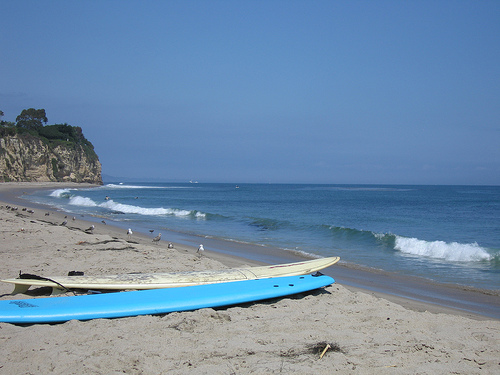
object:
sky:
[1, 1, 499, 184]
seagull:
[195, 243, 206, 254]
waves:
[384, 235, 495, 265]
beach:
[2, 208, 499, 373]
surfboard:
[2, 269, 337, 327]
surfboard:
[3, 254, 341, 290]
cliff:
[0, 106, 105, 188]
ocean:
[5, 180, 499, 287]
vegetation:
[16, 108, 48, 130]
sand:
[0, 178, 497, 375]